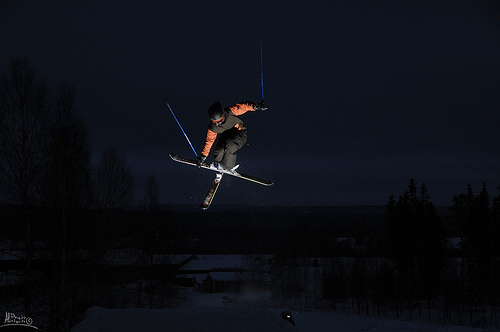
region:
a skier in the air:
[66, 32, 421, 313]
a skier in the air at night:
[123, 38, 483, 284]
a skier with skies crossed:
[112, 24, 342, 227]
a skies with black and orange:
[54, 48, 310, 226]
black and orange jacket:
[157, 29, 301, 193]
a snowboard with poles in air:
[82, 37, 387, 270]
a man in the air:
[107, 32, 436, 282]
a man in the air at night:
[118, 31, 321, 203]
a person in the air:
[121, 29, 360, 279]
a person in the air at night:
[132, 34, 443, 289]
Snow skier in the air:
[152, 47, 290, 213]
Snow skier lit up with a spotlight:
[150, 60, 285, 211]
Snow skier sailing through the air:
[135, 45, 300, 225]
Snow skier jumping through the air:
[145, 40, 286, 206]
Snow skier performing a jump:
[135, 50, 300, 230]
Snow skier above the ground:
[146, 35, 291, 220]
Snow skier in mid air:
[150, 31, 285, 216]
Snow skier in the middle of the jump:
[160, 48, 287, 208]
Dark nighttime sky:
[311, 35, 466, 175]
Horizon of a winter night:
[305, 175, 493, 217]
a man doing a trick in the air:
[86, 25, 431, 330]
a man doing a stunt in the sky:
[114, 6, 354, 330]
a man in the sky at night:
[134, 43, 426, 328]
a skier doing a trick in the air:
[144, 53, 444, 301]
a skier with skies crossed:
[130, 66, 401, 307]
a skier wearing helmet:
[135, 75, 367, 275]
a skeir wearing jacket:
[159, 61, 336, 243]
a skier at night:
[107, 52, 419, 292]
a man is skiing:
[71, 36, 269, 217]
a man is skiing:
[174, 68, 337, 308]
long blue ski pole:
[164, 97, 204, 169]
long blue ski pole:
[253, 36, 270, 108]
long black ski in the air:
[167, 144, 282, 190]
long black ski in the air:
[193, 166, 227, 215]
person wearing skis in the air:
[155, 27, 285, 217]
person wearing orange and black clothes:
[147, 24, 286, 220]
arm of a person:
[230, 95, 270, 120]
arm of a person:
[190, 125, 221, 165]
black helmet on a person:
[208, 103, 225, 127]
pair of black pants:
[209, 129, 251, 167]